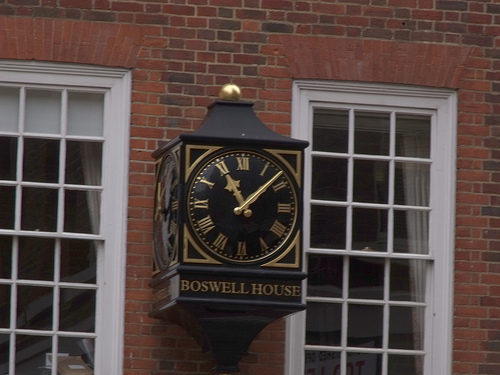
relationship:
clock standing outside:
[146, 83, 311, 365] [2, 2, 484, 371]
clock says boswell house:
[146, 83, 311, 365] [179, 277, 303, 299]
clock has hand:
[146, 83, 311, 365] [225, 173, 253, 219]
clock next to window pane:
[146, 83, 311, 365] [0, 61, 122, 374]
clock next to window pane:
[146, 83, 311, 365] [288, 77, 459, 372]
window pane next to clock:
[0, 61, 122, 374] [146, 83, 311, 365]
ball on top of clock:
[220, 84, 242, 102] [146, 83, 311, 365]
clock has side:
[146, 83, 311, 365] [152, 137, 181, 312]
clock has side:
[146, 83, 311, 365] [180, 138, 302, 309]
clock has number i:
[146, 83, 311, 365] [258, 161, 273, 183]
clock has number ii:
[146, 83, 311, 365] [273, 179, 288, 196]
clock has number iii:
[146, 83, 311, 365] [276, 200, 293, 216]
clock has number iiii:
[146, 83, 311, 365] [269, 219, 287, 239]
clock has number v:
[146, 83, 311, 365] [258, 235, 270, 253]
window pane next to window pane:
[0, 61, 122, 374] [288, 77, 459, 372]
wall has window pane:
[2, 2, 499, 373] [0, 61, 122, 374]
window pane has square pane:
[0, 61, 122, 374] [63, 91, 105, 137]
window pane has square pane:
[0, 61, 122, 374] [23, 88, 64, 138]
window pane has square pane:
[0, 61, 122, 374] [62, 138, 103, 187]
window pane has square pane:
[0, 61, 122, 374] [22, 139, 62, 185]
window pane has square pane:
[0, 61, 122, 374] [19, 186, 58, 232]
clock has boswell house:
[146, 83, 311, 365] [179, 277, 303, 299]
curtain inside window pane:
[76, 139, 107, 244] [0, 61, 122, 374]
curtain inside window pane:
[399, 130, 428, 374] [288, 77, 459, 372]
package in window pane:
[49, 350, 88, 374] [0, 61, 122, 374]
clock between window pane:
[146, 83, 311, 365] [0, 61, 122, 374]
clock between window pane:
[146, 83, 311, 365] [288, 77, 459, 372]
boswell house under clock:
[179, 277, 303, 299] [146, 83, 311, 365]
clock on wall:
[146, 83, 311, 365] [2, 2, 499, 373]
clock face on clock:
[188, 151, 300, 264] [146, 83, 311, 365]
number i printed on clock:
[258, 161, 273, 183] [146, 83, 311, 365]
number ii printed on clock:
[273, 179, 288, 196] [146, 83, 311, 365]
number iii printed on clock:
[276, 200, 293, 216] [146, 83, 311, 365]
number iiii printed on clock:
[269, 219, 287, 239] [146, 83, 311, 365]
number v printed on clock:
[258, 235, 270, 253] [146, 83, 311, 365]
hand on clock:
[225, 173, 253, 219] [146, 83, 311, 365]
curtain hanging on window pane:
[76, 139, 107, 244] [0, 61, 122, 374]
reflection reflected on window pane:
[371, 141, 436, 266] [288, 77, 459, 372]